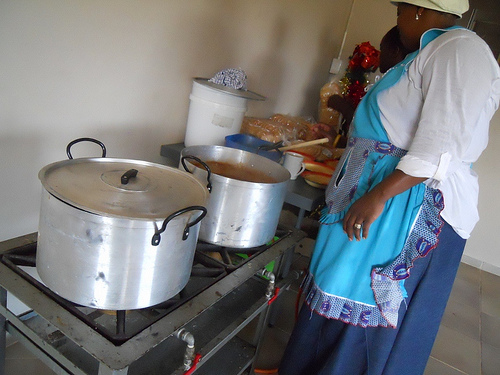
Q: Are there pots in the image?
A: Yes, there is a pot.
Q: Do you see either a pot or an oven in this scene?
A: Yes, there is a pot.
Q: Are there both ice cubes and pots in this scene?
A: No, there is a pot but no ice cubes.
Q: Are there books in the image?
A: No, there are no books.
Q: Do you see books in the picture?
A: No, there are no books.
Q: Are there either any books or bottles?
A: No, there are no books or bottles.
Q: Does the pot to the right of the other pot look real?
A: Yes, the pot is real.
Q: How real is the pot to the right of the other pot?
A: The pot is real.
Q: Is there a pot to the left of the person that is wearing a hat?
A: Yes, there is a pot to the left of the person.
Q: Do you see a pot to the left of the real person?
A: Yes, there is a pot to the left of the person.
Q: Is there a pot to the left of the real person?
A: Yes, there is a pot to the left of the person.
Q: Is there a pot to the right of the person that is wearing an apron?
A: No, the pot is to the left of the person.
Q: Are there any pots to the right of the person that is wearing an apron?
A: No, the pot is to the left of the person.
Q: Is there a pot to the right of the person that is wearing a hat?
A: No, the pot is to the left of the person.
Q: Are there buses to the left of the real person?
A: No, there is a pot to the left of the person.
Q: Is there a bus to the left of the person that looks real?
A: No, there is a pot to the left of the person.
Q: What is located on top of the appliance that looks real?
A: The pot is on top of the stove.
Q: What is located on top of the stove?
A: The pot is on top of the stove.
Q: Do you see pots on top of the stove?
A: Yes, there is a pot on top of the stove.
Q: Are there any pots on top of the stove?
A: Yes, there is a pot on top of the stove.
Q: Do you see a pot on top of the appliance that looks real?
A: Yes, there is a pot on top of the stove.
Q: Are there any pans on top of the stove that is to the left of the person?
A: No, there is a pot on top of the stove.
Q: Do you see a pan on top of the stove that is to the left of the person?
A: No, there is a pot on top of the stove.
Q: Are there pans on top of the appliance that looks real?
A: No, there is a pot on top of the stove.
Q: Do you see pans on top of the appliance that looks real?
A: No, there is a pot on top of the stove.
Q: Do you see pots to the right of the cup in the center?
A: No, the pot is to the left of the cup.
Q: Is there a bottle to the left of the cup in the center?
A: No, there is a pot to the left of the cup.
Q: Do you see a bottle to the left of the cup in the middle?
A: No, there is a pot to the left of the cup.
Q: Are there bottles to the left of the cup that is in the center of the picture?
A: No, there is a pot to the left of the cup.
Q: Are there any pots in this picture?
A: Yes, there is a pot.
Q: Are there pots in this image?
A: Yes, there is a pot.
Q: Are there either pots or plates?
A: Yes, there is a pot.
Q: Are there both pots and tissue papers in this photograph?
A: No, there is a pot but no tissues.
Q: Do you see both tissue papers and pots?
A: No, there is a pot but no tissues.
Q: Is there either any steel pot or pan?
A: Yes, there is a steel pot.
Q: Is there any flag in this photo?
A: No, there are no flags.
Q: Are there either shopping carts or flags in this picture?
A: No, there are no flags or shopping carts.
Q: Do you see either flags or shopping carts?
A: No, there are no flags or shopping carts.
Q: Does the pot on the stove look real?
A: Yes, the pot is real.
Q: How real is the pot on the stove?
A: The pot is real.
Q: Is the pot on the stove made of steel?
A: Yes, the pot is made of steel.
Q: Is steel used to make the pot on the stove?
A: Yes, the pot is made of steel.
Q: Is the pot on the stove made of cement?
A: No, the pot is made of steel.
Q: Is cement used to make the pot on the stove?
A: No, the pot is made of steel.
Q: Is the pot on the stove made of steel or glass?
A: The pot is made of steel.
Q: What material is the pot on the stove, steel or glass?
A: The pot is made of steel.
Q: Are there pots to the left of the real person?
A: Yes, there is a pot to the left of the person.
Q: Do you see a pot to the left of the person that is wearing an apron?
A: Yes, there is a pot to the left of the person.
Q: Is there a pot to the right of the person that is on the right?
A: No, the pot is to the left of the person.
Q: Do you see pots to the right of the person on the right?
A: No, the pot is to the left of the person.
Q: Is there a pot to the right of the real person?
A: No, the pot is to the left of the person.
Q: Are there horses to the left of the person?
A: No, there is a pot to the left of the person.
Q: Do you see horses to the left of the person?
A: No, there is a pot to the left of the person.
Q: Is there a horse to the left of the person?
A: No, there is a pot to the left of the person.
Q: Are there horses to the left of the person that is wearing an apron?
A: No, there is a pot to the left of the person.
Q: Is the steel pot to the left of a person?
A: Yes, the pot is to the left of a person.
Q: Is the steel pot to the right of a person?
A: No, the pot is to the left of a person.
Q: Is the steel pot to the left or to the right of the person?
A: The pot is to the left of the person.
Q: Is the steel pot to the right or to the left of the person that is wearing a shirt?
A: The pot is to the left of the person.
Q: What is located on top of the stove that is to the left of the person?
A: The pot is on top of the stove.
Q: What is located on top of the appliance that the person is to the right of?
A: The pot is on top of the stove.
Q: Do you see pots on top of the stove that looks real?
A: Yes, there is a pot on top of the stove.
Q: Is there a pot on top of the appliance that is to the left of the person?
A: Yes, there is a pot on top of the stove.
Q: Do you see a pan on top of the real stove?
A: No, there is a pot on top of the stove.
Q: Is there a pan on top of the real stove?
A: No, there is a pot on top of the stove.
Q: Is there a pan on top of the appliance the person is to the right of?
A: No, there is a pot on top of the stove.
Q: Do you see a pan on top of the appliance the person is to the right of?
A: No, there is a pot on top of the stove.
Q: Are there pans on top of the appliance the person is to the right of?
A: No, there is a pot on top of the stove.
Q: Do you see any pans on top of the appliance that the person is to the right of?
A: No, there is a pot on top of the stove.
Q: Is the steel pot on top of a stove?
A: Yes, the pot is on top of a stove.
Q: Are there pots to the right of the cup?
A: No, the pot is to the left of the cup.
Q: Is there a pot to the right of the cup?
A: No, the pot is to the left of the cup.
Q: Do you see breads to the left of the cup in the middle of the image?
A: No, there is a pot to the left of the cup.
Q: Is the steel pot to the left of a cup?
A: Yes, the pot is to the left of a cup.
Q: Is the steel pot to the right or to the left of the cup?
A: The pot is to the left of the cup.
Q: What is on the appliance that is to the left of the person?
A: The pot is on the stove.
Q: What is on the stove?
A: The pot is on the stove.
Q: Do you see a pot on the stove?
A: Yes, there is a pot on the stove.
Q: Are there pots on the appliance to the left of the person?
A: Yes, there is a pot on the stove.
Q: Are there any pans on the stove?
A: No, there is a pot on the stove.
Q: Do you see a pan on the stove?
A: No, there is a pot on the stove.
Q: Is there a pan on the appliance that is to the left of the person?
A: No, there is a pot on the stove.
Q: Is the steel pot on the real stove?
A: Yes, the pot is on the stove.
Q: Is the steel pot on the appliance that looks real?
A: Yes, the pot is on the stove.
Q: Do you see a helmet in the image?
A: No, there are no helmets.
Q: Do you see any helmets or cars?
A: No, there are no helmets or cars.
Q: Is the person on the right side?
A: Yes, the person is on the right of the image.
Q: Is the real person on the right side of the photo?
A: Yes, the person is on the right of the image.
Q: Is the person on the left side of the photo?
A: No, the person is on the right of the image.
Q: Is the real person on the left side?
A: No, the person is on the right of the image.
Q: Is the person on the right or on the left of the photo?
A: The person is on the right of the image.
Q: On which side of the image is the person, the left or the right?
A: The person is on the right of the image.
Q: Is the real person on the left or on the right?
A: The person is on the right of the image.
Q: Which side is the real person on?
A: The person is on the right of the image.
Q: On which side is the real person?
A: The person is on the right of the image.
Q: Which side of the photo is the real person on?
A: The person is on the right of the image.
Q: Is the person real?
A: Yes, the person is real.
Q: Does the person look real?
A: Yes, the person is real.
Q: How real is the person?
A: The person is real.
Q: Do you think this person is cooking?
A: Yes, the person is cooking.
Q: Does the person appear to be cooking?
A: Yes, the person is cooking.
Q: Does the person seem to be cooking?
A: Yes, the person is cooking.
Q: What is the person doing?
A: The person is cooking.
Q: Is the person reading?
A: No, the person is cooking.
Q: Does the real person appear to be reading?
A: No, the person is cooking.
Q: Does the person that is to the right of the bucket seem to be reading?
A: No, the person is cooking.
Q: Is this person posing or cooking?
A: The person is cooking.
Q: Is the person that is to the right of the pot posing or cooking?
A: The person is cooking.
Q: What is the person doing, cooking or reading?
A: The person is cooking.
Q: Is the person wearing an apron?
A: Yes, the person is wearing an apron.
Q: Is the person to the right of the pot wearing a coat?
A: No, the person is wearing an apron.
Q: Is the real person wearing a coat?
A: No, the person is wearing an apron.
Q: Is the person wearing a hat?
A: Yes, the person is wearing a hat.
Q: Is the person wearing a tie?
A: No, the person is wearing a hat.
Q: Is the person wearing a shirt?
A: Yes, the person is wearing a shirt.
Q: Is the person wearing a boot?
A: No, the person is wearing a shirt.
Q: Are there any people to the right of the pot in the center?
A: Yes, there is a person to the right of the pot.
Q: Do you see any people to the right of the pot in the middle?
A: Yes, there is a person to the right of the pot.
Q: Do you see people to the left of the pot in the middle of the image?
A: No, the person is to the right of the pot.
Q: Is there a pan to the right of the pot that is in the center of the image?
A: No, there is a person to the right of the pot.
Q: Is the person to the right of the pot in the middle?
A: Yes, the person is to the right of the pot.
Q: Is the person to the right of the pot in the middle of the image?
A: Yes, the person is to the right of the pot.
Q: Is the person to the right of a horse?
A: No, the person is to the right of the pot.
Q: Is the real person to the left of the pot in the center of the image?
A: No, the person is to the right of the pot.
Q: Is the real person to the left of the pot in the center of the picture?
A: No, the person is to the right of the pot.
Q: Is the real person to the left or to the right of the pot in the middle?
A: The person is to the right of the pot.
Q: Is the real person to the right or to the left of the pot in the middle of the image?
A: The person is to the right of the pot.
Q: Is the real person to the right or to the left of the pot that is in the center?
A: The person is to the right of the pot.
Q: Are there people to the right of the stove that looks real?
A: Yes, there is a person to the right of the stove.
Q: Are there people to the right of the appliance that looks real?
A: Yes, there is a person to the right of the stove.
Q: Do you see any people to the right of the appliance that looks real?
A: Yes, there is a person to the right of the stove.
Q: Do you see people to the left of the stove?
A: No, the person is to the right of the stove.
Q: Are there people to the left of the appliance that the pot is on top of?
A: No, the person is to the right of the stove.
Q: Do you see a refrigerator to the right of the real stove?
A: No, there is a person to the right of the stove.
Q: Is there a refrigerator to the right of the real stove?
A: No, there is a person to the right of the stove.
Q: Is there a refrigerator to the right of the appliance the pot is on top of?
A: No, there is a person to the right of the stove.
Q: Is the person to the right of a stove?
A: Yes, the person is to the right of a stove.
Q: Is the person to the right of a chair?
A: No, the person is to the right of a stove.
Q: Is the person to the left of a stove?
A: No, the person is to the right of a stove.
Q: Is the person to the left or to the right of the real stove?
A: The person is to the right of the stove.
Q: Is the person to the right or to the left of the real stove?
A: The person is to the right of the stove.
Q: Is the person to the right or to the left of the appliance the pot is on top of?
A: The person is to the right of the stove.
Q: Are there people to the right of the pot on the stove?
A: Yes, there is a person to the right of the pot.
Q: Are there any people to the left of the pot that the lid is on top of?
A: No, the person is to the right of the pot.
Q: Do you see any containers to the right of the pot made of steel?
A: No, there is a person to the right of the pot.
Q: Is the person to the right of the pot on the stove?
A: Yes, the person is to the right of the pot.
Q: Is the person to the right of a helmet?
A: No, the person is to the right of the pot.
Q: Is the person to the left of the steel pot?
A: No, the person is to the right of the pot.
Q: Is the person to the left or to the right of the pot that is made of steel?
A: The person is to the right of the pot.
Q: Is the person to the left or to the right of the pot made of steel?
A: The person is to the right of the pot.